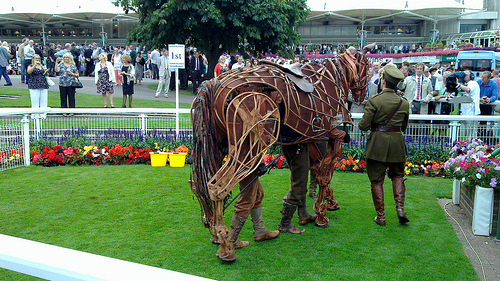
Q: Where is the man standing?
A: Next to the horse.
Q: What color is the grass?
A: Green.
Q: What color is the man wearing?
A: Green.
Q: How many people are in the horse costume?
A: Two.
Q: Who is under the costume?
A: Two men.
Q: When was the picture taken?
A: During the day.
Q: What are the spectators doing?
A: Watching.